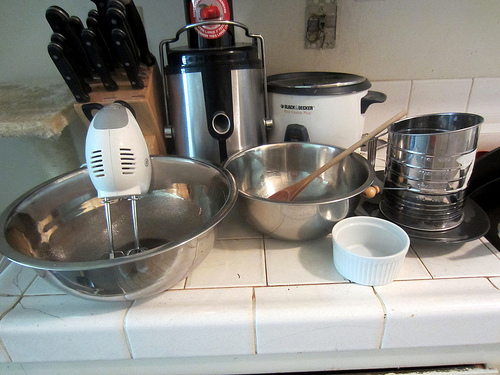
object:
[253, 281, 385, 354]
tiles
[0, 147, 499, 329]
counter top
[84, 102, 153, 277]
hand mixer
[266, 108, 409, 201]
spoon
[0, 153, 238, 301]
bowl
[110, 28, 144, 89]
handles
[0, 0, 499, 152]
wall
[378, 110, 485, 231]
sifter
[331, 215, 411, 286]
bowl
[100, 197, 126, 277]
blades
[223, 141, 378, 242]
bowl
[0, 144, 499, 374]
counter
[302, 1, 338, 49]
socket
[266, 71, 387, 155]
crock pot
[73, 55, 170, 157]
block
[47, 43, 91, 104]
knife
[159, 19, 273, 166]
appliance